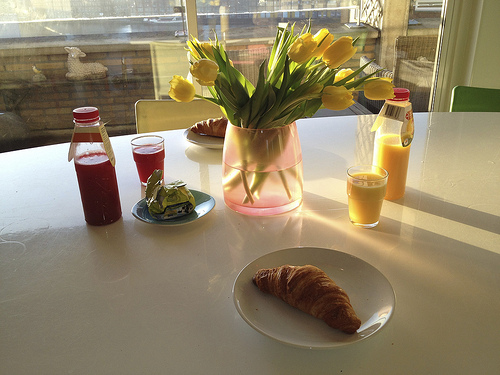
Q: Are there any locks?
A: No, there are no locks.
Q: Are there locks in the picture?
A: No, there are no locks.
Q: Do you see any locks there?
A: No, there are no locks.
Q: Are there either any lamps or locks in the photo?
A: No, there are no locks or lamps.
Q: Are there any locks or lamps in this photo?
A: No, there are no locks or lamps.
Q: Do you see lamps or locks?
A: No, there are no locks or lamps.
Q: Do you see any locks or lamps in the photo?
A: No, there are no locks or lamps.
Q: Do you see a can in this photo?
A: No, there are no cans.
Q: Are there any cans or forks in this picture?
A: No, there are no cans or forks.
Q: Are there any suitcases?
A: No, there are no suitcases.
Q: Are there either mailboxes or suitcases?
A: No, there are no suitcases or mailboxes.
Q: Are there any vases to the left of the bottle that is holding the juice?
A: Yes, there is a vase to the left of the bottle.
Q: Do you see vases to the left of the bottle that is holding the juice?
A: Yes, there is a vase to the left of the bottle.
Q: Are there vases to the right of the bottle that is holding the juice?
A: No, the vase is to the left of the bottle.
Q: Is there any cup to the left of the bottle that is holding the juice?
A: No, there is a vase to the left of the bottle.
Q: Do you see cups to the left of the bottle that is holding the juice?
A: No, there is a vase to the left of the bottle.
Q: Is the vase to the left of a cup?
A: No, the vase is to the left of a bottle.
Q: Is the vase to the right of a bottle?
A: No, the vase is to the left of a bottle.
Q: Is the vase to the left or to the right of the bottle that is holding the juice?
A: The vase is to the left of the bottle.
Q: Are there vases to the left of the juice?
A: Yes, there is a vase to the left of the juice.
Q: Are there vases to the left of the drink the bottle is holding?
A: Yes, there is a vase to the left of the juice.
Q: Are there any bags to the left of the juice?
A: No, there is a vase to the left of the juice.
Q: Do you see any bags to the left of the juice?
A: No, there is a vase to the left of the juice.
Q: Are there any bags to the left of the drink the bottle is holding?
A: No, there is a vase to the left of the juice.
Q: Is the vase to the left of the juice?
A: Yes, the vase is to the left of the juice.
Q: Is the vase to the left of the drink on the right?
A: Yes, the vase is to the left of the juice.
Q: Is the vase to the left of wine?
A: No, the vase is to the left of the juice.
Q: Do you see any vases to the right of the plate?
A: Yes, there is a vase to the right of the plate.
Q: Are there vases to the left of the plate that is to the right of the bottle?
A: No, the vase is to the right of the plate.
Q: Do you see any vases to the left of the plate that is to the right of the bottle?
A: No, the vase is to the right of the plate.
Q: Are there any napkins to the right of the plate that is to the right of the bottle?
A: No, there is a vase to the right of the plate.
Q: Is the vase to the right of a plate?
A: Yes, the vase is to the right of a plate.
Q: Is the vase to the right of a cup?
A: No, the vase is to the right of a plate.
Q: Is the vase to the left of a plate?
A: No, the vase is to the right of a plate.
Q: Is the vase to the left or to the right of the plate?
A: The vase is to the right of the plate.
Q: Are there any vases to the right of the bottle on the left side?
A: Yes, there is a vase to the right of the bottle.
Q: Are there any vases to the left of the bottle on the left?
A: No, the vase is to the right of the bottle.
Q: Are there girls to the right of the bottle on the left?
A: No, there is a vase to the right of the bottle.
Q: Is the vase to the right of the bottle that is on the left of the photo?
A: Yes, the vase is to the right of the bottle.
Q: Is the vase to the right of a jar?
A: No, the vase is to the right of the bottle.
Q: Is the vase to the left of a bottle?
A: No, the vase is to the right of a bottle.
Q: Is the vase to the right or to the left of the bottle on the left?
A: The vase is to the right of the bottle.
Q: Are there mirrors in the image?
A: No, there are no mirrors.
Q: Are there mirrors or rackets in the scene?
A: No, there are no mirrors or rackets.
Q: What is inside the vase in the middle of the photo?
A: The flowers are inside the vase.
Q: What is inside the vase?
A: The flowers are inside the vase.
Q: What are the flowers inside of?
A: The flowers are inside the vase.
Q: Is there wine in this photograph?
A: No, there is no wine.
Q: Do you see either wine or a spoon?
A: No, there are no wine or spoons.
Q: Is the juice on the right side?
A: Yes, the juice is on the right of the image.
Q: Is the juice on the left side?
A: No, the juice is on the right of the image.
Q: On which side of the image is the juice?
A: The juice is on the right of the image.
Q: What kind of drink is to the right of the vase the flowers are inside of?
A: The drink is juice.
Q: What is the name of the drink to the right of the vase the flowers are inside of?
A: The drink is juice.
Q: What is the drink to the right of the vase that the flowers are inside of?
A: The drink is juice.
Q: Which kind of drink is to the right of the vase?
A: The drink is juice.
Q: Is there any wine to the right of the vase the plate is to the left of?
A: No, there is juice to the right of the vase.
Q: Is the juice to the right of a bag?
A: No, the juice is to the right of a vase.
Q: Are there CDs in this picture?
A: No, there are no cds.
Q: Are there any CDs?
A: No, there are no cds.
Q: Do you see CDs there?
A: No, there are no cds.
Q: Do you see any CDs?
A: No, there are no cds.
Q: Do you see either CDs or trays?
A: No, there are no CDs or trays.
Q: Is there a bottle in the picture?
A: Yes, there is a bottle.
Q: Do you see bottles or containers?
A: Yes, there is a bottle.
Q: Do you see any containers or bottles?
A: Yes, there is a bottle.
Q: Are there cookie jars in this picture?
A: No, there are no cookie jars.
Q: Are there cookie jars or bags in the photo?
A: No, there are no cookie jars or bags.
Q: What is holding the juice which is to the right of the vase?
A: The bottle is holding the juice.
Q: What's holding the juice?
A: The bottle is holding the juice.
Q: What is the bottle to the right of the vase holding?
A: The bottle is holding the juice.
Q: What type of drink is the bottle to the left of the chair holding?
A: The bottle is holding the juice.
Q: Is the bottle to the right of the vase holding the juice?
A: Yes, the bottle is holding the juice.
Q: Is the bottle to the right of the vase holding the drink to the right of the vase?
A: Yes, the bottle is holding the juice.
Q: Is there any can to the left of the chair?
A: No, there is a bottle to the left of the chair.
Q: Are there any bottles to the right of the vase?
A: Yes, there is a bottle to the right of the vase.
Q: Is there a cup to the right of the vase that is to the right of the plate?
A: No, there is a bottle to the right of the vase.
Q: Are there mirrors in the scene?
A: No, there are no mirrors.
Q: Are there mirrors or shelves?
A: No, there are no mirrors or shelves.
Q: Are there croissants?
A: Yes, there is a croissant.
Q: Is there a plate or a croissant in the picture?
A: Yes, there is a croissant.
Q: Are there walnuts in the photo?
A: No, there are no walnuts.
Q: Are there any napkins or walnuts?
A: No, there are no walnuts or napkins.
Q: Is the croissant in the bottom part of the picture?
A: Yes, the croissant is in the bottom of the image.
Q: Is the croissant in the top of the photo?
A: No, the croissant is in the bottom of the image.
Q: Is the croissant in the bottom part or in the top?
A: The croissant is in the bottom of the image.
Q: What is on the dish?
A: The croissant is on the dish.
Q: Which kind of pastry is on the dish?
A: The pastry is a croissant.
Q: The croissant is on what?
A: The croissant is on the dish.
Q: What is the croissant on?
A: The croissant is on the dish.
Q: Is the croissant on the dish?
A: Yes, the croissant is on the dish.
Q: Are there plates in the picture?
A: Yes, there is a plate.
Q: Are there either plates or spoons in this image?
A: Yes, there is a plate.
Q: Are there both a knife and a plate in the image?
A: No, there is a plate but no knives.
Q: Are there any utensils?
A: No, there are no utensils.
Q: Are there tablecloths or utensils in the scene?
A: No, there are no utensils or tablecloths.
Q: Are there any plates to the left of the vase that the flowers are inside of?
A: Yes, there is a plate to the left of the vase.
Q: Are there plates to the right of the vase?
A: No, the plate is to the left of the vase.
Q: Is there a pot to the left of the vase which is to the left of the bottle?
A: No, there is a plate to the left of the vase.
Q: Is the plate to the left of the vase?
A: Yes, the plate is to the left of the vase.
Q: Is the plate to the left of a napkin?
A: No, the plate is to the left of the vase.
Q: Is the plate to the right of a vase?
A: No, the plate is to the left of a vase.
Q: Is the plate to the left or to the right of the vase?
A: The plate is to the left of the vase.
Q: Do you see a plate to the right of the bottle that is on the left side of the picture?
A: Yes, there is a plate to the right of the bottle.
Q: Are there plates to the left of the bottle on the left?
A: No, the plate is to the right of the bottle.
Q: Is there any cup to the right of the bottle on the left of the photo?
A: No, there is a plate to the right of the bottle.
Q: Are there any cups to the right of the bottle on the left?
A: No, there is a plate to the right of the bottle.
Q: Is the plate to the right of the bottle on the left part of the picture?
A: Yes, the plate is to the right of the bottle.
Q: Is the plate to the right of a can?
A: No, the plate is to the right of the bottle.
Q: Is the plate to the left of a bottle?
A: No, the plate is to the right of a bottle.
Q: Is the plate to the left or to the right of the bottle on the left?
A: The plate is to the right of the bottle.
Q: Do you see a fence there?
A: No, there are no fences.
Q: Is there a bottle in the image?
A: Yes, there is a bottle.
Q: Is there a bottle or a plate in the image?
A: Yes, there is a bottle.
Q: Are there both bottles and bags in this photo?
A: No, there is a bottle but no bags.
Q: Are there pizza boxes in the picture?
A: No, there are no pizza boxes.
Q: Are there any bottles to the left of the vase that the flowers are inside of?
A: Yes, there is a bottle to the left of the vase.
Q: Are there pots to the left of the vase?
A: No, there is a bottle to the left of the vase.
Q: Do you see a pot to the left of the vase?
A: No, there is a bottle to the left of the vase.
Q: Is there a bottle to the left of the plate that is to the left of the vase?
A: Yes, there is a bottle to the left of the plate.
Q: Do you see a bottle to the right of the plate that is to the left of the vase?
A: No, the bottle is to the left of the plate.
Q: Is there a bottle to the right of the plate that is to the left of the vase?
A: No, the bottle is to the left of the plate.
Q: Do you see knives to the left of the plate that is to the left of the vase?
A: No, there is a bottle to the left of the plate.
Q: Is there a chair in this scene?
A: Yes, there is a chair.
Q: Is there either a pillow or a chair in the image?
A: Yes, there is a chair.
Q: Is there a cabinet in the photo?
A: No, there are no cabinets.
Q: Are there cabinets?
A: No, there are no cabinets.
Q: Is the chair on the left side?
A: No, the chair is on the right of the image.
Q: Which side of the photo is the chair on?
A: The chair is on the right of the image.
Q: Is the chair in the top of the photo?
A: Yes, the chair is in the top of the image.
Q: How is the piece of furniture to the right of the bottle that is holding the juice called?
A: The piece of furniture is a chair.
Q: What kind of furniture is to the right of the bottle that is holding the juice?
A: The piece of furniture is a chair.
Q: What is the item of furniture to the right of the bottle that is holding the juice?
A: The piece of furniture is a chair.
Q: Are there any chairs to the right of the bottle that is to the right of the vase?
A: Yes, there is a chair to the right of the bottle.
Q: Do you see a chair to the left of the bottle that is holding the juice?
A: No, the chair is to the right of the bottle.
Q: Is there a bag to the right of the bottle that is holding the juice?
A: No, there is a chair to the right of the bottle.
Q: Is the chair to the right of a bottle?
A: Yes, the chair is to the right of a bottle.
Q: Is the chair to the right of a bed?
A: No, the chair is to the right of a bottle.